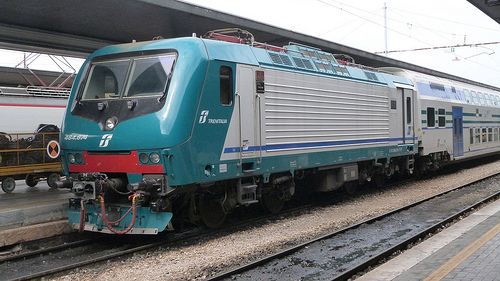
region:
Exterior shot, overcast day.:
[5, 3, 499, 278]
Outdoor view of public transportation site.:
[6, 5, 498, 276]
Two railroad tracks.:
[44, 242, 400, 280]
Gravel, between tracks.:
[173, 232, 270, 266]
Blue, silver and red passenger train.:
[60, 37, 492, 213]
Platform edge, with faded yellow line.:
[418, 216, 499, 274]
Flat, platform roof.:
[111, 2, 342, 44]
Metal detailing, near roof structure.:
[4, 52, 73, 89]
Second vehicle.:
[0, 79, 62, 191]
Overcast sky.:
[351, 10, 455, 48]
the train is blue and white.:
[45, 2, 497, 212]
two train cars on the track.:
[55, 10, 487, 182]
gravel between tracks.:
[72, 158, 488, 261]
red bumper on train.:
[40, 126, 191, 193]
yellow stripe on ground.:
[436, 203, 498, 273]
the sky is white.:
[207, 3, 487, 84]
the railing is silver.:
[227, 86, 274, 188]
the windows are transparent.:
[94, 49, 181, 116]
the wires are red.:
[70, 176, 150, 245]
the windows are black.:
[395, 79, 455, 144]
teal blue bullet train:
[63, 26, 490, 235]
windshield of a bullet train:
[72, 33, 187, 129]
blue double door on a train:
[446, 101, 476, 173]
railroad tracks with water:
[271, 233, 335, 274]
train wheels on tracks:
[189, 171, 364, 228]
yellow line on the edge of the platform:
[418, 221, 491, 275]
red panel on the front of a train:
[56, 138, 180, 193]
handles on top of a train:
[200, 16, 398, 73]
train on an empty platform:
[57, 22, 482, 268]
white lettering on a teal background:
[196, 106, 256, 147]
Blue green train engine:
[57, 34, 419, 246]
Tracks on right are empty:
[194, 158, 493, 274]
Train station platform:
[364, 179, 499, 279]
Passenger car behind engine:
[381, 59, 498, 175]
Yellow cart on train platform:
[0, 125, 67, 192]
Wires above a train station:
[314, 0, 498, 92]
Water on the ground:
[292, 216, 418, 279]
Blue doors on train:
[448, 101, 470, 157]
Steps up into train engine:
[233, 93, 264, 236]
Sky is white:
[228, 2, 497, 84]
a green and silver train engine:
[58, 32, 419, 237]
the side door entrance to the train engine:
[236, 65, 257, 171]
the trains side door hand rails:
[236, 92, 244, 169]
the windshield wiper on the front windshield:
[158, 58, 177, 103]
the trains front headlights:
[137, 150, 159, 164]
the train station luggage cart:
[2, 123, 61, 193]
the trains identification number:
[63, 132, 89, 142]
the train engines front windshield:
[80, 53, 176, 102]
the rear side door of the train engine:
[400, 85, 415, 146]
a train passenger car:
[417, 68, 499, 173]